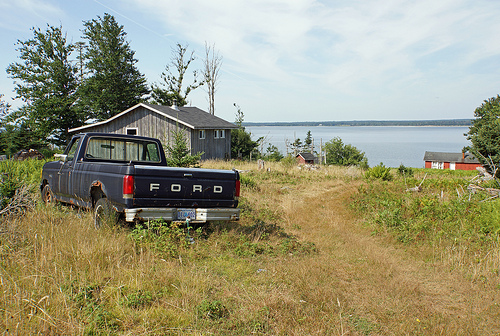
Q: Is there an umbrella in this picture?
A: No, there are no umbrellas.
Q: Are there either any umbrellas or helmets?
A: No, there are no umbrellas or helmets.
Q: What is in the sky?
A: The clouds are in the sky.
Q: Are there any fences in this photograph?
A: No, there are no fences.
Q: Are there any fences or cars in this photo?
A: No, there are no fences or cars.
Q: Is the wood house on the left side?
A: Yes, the house is on the left of the image.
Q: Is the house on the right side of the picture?
A: No, the house is on the left of the image.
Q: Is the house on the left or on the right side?
A: The house is on the left of the image.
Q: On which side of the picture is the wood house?
A: The house is on the left of the image.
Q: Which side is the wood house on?
A: The house is on the left of the image.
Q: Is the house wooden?
A: Yes, the house is wooden.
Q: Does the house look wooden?
A: Yes, the house is wooden.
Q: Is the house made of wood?
A: Yes, the house is made of wood.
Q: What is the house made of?
A: The house is made of wood.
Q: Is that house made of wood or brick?
A: The house is made of wood.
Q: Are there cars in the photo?
A: No, there are no cars.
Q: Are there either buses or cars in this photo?
A: No, there are no cars or buses.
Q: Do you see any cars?
A: No, there are no cars.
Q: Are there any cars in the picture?
A: No, there are no cars.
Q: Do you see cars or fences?
A: No, there are no cars or fences.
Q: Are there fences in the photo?
A: No, there are no fences.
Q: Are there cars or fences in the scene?
A: No, there are no fences or cars.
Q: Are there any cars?
A: No, there are no cars.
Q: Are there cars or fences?
A: No, there are no cars or fences.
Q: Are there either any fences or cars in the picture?
A: No, there are no cars or fences.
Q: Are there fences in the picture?
A: No, there are no fences.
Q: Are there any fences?
A: No, there are no fences.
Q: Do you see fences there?
A: No, there are no fences.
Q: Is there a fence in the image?
A: No, there are no fences.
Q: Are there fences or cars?
A: No, there are no fences or cars.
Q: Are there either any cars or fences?
A: No, there are no fences or cars.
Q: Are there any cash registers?
A: No, there are no cash registers.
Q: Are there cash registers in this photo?
A: No, there are no cash registers.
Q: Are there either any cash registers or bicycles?
A: No, there are no cash registers or bicycles.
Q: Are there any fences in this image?
A: No, there are no fences.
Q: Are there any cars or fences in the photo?
A: No, there are no fences or cars.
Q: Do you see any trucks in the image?
A: Yes, there is a truck.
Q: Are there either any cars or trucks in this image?
A: Yes, there is a truck.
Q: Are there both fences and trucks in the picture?
A: No, there is a truck but no fences.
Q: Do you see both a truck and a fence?
A: No, there is a truck but no fences.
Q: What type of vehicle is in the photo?
A: The vehicle is a truck.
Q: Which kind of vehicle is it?
A: The vehicle is a truck.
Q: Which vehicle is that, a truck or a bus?
A: That is a truck.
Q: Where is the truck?
A: The truck is on the grass.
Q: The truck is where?
A: The truck is on the grass.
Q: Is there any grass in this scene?
A: Yes, there is grass.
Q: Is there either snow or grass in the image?
A: Yes, there is grass.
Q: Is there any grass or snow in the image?
A: Yes, there is grass.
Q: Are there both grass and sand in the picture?
A: No, there is grass but no sand.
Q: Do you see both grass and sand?
A: No, there is grass but no sand.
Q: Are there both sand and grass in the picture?
A: No, there is grass but no sand.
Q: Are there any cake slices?
A: No, there are no cake slices.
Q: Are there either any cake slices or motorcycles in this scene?
A: No, there are no cake slices or motorcycles.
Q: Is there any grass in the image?
A: Yes, there is grass.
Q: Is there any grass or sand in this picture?
A: Yes, there is grass.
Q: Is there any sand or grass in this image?
A: Yes, there is grass.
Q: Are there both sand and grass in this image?
A: No, there is grass but no sand.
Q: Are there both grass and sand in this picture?
A: No, there is grass but no sand.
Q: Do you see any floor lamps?
A: No, there are no floor lamps.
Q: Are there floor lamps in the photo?
A: No, there are no floor lamps.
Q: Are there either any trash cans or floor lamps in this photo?
A: No, there are no floor lamps or trash cans.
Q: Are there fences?
A: No, there are no fences.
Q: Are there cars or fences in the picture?
A: No, there are no fences or cars.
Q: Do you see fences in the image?
A: No, there are no fences.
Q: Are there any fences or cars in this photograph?
A: No, there are no fences or cars.